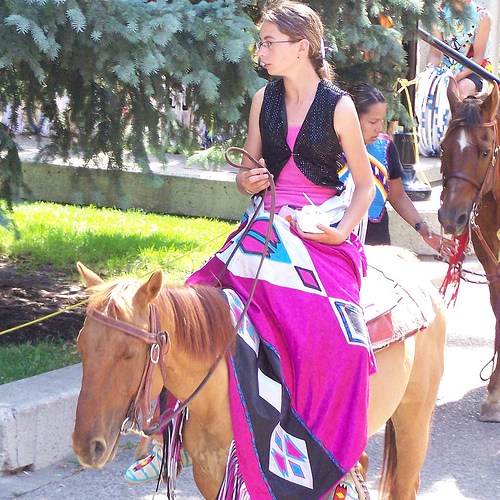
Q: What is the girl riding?
A: Horse.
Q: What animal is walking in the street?
A: Horse.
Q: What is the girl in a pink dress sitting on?
A: Horse.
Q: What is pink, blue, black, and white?
A: Dress.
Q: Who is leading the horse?
A: The woman.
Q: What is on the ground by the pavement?
A: Green grass.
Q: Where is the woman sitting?
A: On a horse.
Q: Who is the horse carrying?
A: The girl.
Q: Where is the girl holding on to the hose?
A: The reins.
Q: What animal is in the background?
A: A horse.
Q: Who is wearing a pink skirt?
A: The girl.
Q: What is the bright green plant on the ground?
A: Grass.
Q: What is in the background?
A: Part of a pine tree.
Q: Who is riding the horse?
A: A girl.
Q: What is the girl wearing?
A: A vest.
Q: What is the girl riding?
A: A horse.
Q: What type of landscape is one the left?
A: Grass.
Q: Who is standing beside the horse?
A: A girl.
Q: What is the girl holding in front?
A: Reins.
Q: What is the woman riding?
A: A horse.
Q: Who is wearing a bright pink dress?
A: Woman on horse.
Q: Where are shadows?
A: On the ground.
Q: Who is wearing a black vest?
A: A woman.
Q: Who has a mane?
A: The horse.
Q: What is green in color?
A: Grass.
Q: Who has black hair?
A: The woman standing.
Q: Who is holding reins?
A: Woman on top of horse.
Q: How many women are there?
A: 2.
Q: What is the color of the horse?
A: Brown.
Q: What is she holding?
A: A drink.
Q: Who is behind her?
A: A woman.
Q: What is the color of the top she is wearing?
A: Pink.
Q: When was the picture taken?
A: During the day.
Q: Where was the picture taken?
A: At a parade.